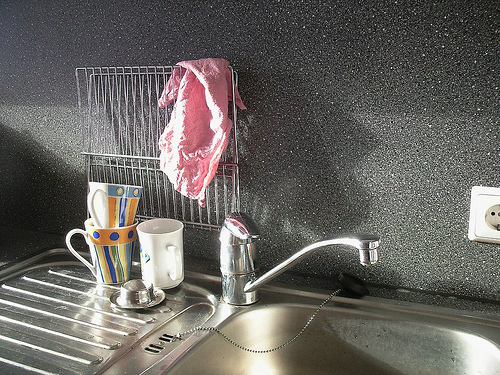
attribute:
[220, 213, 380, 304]
faucet — silver, shiny, metal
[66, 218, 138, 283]
cup — stacked, striped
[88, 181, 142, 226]
cup — stacked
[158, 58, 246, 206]
cloth — pink, hanging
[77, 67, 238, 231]
rack — white, silver wire, silver, folded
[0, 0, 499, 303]
wall — gray, gray granite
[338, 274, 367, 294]
stopper — black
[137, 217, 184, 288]
cup — white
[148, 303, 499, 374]
sink — stainless steel